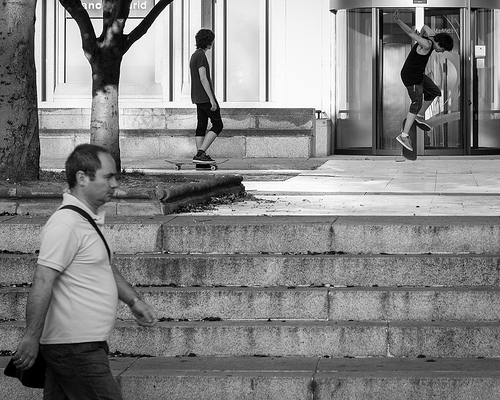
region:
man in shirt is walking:
[9, 136, 165, 398]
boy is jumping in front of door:
[387, 5, 487, 194]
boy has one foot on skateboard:
[177, 21, 239, 188]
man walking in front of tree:
[21, 141, 176, 398]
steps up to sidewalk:
[199, 163, 306, 398]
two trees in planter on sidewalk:
[0, 1, 197, 223]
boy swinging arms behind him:
[348, 2, 483, 77]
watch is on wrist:
[125, 178, 176, 379]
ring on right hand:
[0, 327, 65, 382]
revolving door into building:
[333, 15, 494, 163]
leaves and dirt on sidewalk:
[137, 153, 326, 233]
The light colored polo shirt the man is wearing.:
[32, 182, 127, 345]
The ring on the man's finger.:
[17, 355, 24, 362]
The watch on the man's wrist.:
[124, 294, 143, 306]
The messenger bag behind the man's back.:
[4, 327, 54, 382]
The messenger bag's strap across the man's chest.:
[60, 198, 125, 271]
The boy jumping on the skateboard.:
[388, 10, 460, 162]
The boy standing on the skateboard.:
[181, 21, 242, 171]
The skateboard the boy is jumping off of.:
[400, 118, 422, 163]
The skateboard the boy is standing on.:
[158, 156, 238, 168]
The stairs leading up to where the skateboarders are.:
[9, 205, 497, 399]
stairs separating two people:
[20, 25, 291, 383]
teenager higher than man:
[31, 20, 257, 360]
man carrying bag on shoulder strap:
[40, 135, 160, 352]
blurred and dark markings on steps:
[180, 216, 456, 386]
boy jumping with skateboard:
[305, 1, 480, 161]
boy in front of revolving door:
[325, 6, 491, 166]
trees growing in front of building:
[1, 12, 186, 202]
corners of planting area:
[120, 155, 255, 215]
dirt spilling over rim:
[186, 161, 377, 221]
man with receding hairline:
[48, 127, 128, 237]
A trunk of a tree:
[32, 3, 142, 174]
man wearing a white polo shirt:
[23, 180, 125, 360]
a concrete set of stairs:
[186, 181, 477, 397]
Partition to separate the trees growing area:
[105, 122, 255, 221]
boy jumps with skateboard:
[387, 13, 444, 162]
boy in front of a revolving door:
[318, 3, 498, 158]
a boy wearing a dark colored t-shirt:
[180, 23, 230, 107]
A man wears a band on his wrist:
[121, 280, 158, 335]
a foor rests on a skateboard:
[165, 148, 231, 177]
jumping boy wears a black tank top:
[396, 13, 456, 86]